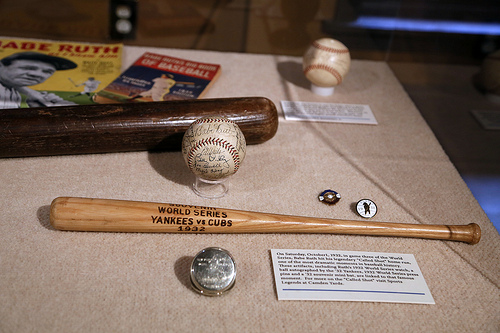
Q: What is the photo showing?
A: It is showing a display.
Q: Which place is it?
A: It is a display.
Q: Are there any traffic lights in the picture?
A: No, there are no traffic lights.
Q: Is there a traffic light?
A: No, there are no traffic lights.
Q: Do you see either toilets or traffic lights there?
A: No, there are no traffic lights or toilets.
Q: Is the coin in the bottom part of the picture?
A: Yes, the coin is in the bottom of the image.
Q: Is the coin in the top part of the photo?
A: No, the coin is in the bottom of the image.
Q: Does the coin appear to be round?
A: Yes, the coin is round.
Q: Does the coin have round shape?
A: Yes, the coin is round.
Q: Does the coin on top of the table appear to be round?
A: Yes, the coin is round.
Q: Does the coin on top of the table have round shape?
A: Yes, the coin is round.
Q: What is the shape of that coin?
A: The coin is round.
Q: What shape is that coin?
A: The coin is round.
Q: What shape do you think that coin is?
A: The coin is round.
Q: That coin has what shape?
A: The coin is round.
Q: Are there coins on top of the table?
A: Yes, there is a coin on top of the table.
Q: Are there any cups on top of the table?
A: No, there is a coin on top of the table.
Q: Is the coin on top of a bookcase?
A: No, the coin is on top of the table.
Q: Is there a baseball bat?
A: Yes, there is a baseball bat.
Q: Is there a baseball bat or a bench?
A: Yes, there is a baseball bat.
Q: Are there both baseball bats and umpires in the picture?
A: No, there is a baseball bat but no umpires.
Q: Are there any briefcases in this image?
A: No, there are no briefcases.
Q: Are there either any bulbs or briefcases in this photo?
A: No, there are no briefcases or bulbs.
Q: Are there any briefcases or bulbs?
A: No, there are no briefcases or bulbs.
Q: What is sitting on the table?
A: The baseball bat is sitting on the table.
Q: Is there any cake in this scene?
A: No, there are no cakes.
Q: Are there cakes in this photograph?
A: No, there are no cakes.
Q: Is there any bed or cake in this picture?
A: No, there are no cakes or beds.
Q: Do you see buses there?
A: No, there are no buses.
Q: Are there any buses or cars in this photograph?
A: No, there are no buses or cars.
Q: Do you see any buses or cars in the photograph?
A: No, there are no buses or cars.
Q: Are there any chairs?
A: No, there are no chairs.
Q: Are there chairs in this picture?
A: No, there are no chairs.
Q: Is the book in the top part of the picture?
A: Yes, the book is in the top of the image.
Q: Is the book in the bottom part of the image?
A: No, the book is in the top of the image.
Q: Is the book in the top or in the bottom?
A: The book is in the top of the image.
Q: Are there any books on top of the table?
A: Yes, there is a book on top of the table.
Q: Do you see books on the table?
A: Yes, there is a book on the table.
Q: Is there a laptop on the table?
A: No, there is a book on the table.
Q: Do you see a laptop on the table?
A: No, there is a book on the table.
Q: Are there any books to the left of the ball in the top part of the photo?
A: Yes, there is a book to the left of the ball.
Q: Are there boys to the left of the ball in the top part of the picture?
A: No, there is a book to the left of the ball.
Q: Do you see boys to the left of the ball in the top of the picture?
A: No, there is a book to the left of the ball.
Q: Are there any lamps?
A: No, there are no lamps.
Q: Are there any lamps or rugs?
A: No, there are no lamps or rugs.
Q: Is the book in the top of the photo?
A: Yes, the book is in the top of the image.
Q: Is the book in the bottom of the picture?
A: No, the book is in the top of the image.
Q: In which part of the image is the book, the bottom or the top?
A: The book is in the top of the image.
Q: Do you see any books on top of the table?
A: Yes, there is a book on top of the table.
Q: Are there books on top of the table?
A: Yes, there is a book on top of the table.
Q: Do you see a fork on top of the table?
A: No, there is a book on top of the table.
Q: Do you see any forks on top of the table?
A: No, there is a book on top of the table.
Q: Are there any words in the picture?
A: Yes, there are words.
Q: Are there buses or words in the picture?
A: Yes, there are words.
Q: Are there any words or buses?
A: Yes, there are words.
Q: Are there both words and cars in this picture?
A: No, there are words but no cars.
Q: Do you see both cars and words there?
A: No, there are words but no cars.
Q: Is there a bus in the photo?
A: No, there are no buses.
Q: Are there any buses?
A: No, there are no buses.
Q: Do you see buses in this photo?
A: No, there are no buses.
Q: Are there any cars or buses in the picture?
A: No, there are no buses or cars.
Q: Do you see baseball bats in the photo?
A: Yes, there is a baseball bat.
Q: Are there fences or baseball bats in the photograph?
A: Yes, there is a baseball bat.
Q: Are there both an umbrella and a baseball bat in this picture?
A: No, there is a baseball bat but no umbrellas.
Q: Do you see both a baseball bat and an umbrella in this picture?
A: No, there is a baseball bat but no umbrellas.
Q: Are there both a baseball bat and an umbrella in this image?
A: No, there is a baseball bat but no umbrellas.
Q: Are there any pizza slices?
A: No, there are no pizza slices.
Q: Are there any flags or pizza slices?
A: No, there are no pizza slices or flags.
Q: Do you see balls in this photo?
A: Yes, there is a ball.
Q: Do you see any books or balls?
A: Yes, there is a ball.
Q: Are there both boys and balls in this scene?
A: No, there is a ball but no boys.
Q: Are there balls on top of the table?
A: Yes, there is a ball on top of the table.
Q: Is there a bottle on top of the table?
A: No, there is a ball on top of the table.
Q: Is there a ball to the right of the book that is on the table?
A: Yes, there is a ball to the right of the book.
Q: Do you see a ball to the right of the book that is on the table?
A: Yes, there is a ball to the right of the book.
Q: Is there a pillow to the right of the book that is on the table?
A: No, there is a ball to the right of the book.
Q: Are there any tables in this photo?
A: Yes, there is a table.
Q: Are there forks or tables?
A: Yes, there is a table.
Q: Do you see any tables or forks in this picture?
A: Yes, there is a table.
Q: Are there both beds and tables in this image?
A: No, there is a table but no beds.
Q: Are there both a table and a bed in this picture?
A: No, there is a table but no beds.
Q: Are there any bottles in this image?
A: No, there are no bottles.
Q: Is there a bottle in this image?
A: No, there are no bottles.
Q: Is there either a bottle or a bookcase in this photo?
A: No, there are no bottles or bookcases.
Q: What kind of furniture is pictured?
A: The furniture is a table.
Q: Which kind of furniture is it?
A: The piece of furniture is a table.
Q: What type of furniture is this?
A: This is a table.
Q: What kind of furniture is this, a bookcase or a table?
A: This is a table.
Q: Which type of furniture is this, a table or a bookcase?
A: This is a table.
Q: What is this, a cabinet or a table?
A: This is a table.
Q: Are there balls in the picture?
A: Yes, there is a ball.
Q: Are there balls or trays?
A: Yes, there is a ball.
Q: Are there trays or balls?
A: Yes, there is a ball.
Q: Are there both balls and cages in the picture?
A: No, there is a ball but no cages.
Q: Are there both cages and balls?
A: No, there is a ball but no cages.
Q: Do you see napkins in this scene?
A: No, there are no napkins.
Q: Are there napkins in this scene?
A: No, there are no napkins.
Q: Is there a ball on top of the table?
A: Yes, there is a ball on top of the table.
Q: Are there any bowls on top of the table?
A: No, there is a ball on top of the table.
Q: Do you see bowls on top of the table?
A: No, there is a ball on top of the table.